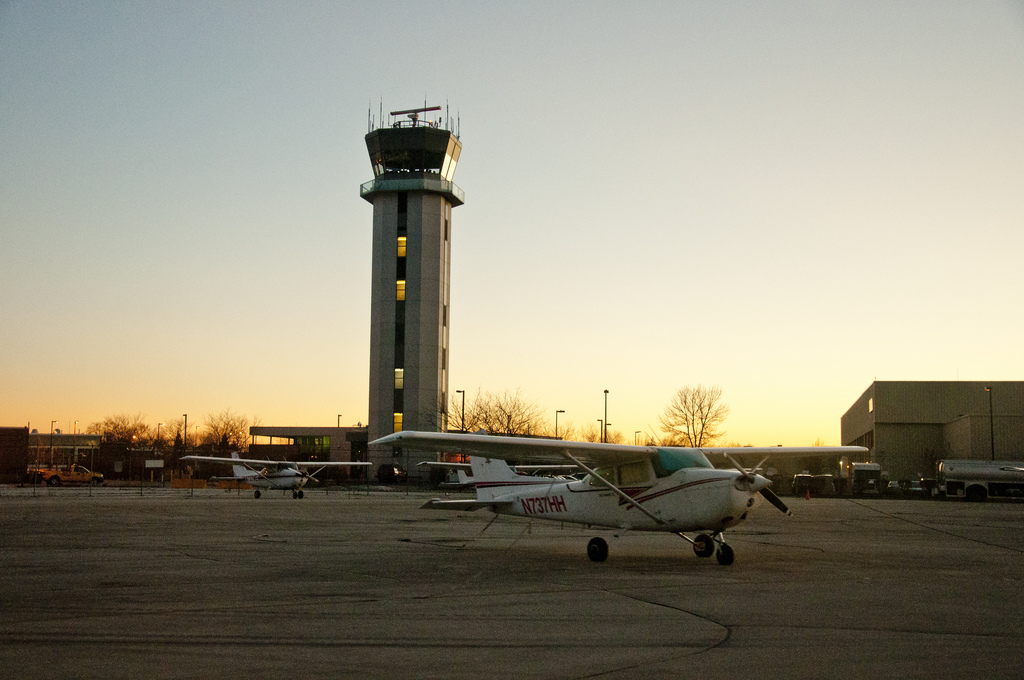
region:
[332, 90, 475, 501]
the tower of an airport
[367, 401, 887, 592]
the plane is color white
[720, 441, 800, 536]
the propeller of a plane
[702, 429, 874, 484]
the wing is white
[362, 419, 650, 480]
the wing is white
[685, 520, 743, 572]
front wheel of plane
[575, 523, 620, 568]
back wheel of a plane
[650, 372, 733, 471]
a tree behind a plane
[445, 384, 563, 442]
a tree behind a plane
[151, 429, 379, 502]
a plane on the ground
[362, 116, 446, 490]
an airplane tower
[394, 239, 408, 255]
a window on the airplane tower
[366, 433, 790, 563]
a small white airplane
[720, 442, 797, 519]
the propeller on the airplane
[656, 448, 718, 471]
the windshield on the plane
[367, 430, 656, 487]
the wing on the plane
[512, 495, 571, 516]
numbers on the plane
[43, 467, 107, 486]
a yellow truck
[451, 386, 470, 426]
a black lamp post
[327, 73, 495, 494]
this is a traffic control tower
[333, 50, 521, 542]
an air traffic control tower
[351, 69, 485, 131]
antennas on top of the tower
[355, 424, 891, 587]
a small white airplane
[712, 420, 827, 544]
this is the propeller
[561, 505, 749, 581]
these are the wheels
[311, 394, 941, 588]
the plane is on the tarmac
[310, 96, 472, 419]
air traffic tower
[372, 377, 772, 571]
white plane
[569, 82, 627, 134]
white clouds in blue sky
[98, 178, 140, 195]
white clouds in blue sky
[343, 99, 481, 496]
a communication control tower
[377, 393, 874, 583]
a small private airplane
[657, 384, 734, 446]
A tree in a city.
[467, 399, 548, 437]
A tree in a city.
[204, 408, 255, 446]
A tree in a city.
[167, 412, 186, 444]
A tree in a city.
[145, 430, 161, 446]
A tree in a city.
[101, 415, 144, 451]
A tree in a city.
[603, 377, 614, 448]
A tall street light.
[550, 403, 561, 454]
A tall street light.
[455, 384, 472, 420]
A tall street light.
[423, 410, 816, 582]
A plane on the runway.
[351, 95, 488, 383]
Airport tower on the terminal.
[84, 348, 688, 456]
The sun is setting.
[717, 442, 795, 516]
Propeller in front of the plane.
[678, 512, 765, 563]
Landing gear on the plane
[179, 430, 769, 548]
Planes on the terminal.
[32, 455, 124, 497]
A yellow truck by the building.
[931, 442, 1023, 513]
A truck by the building.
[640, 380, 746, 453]
A tree behind the building.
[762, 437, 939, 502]
Vehicles parked by the building.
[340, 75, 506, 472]
a tall building on runway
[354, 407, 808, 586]
a plane on the runway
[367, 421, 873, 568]
small airplane on a runway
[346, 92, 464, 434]
an airport tower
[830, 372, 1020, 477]
light colored brick building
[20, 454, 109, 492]
car parked in the distance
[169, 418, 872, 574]
two airplanes in a parking lot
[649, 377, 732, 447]
tree with no leaves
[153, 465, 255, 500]
orange safety fence